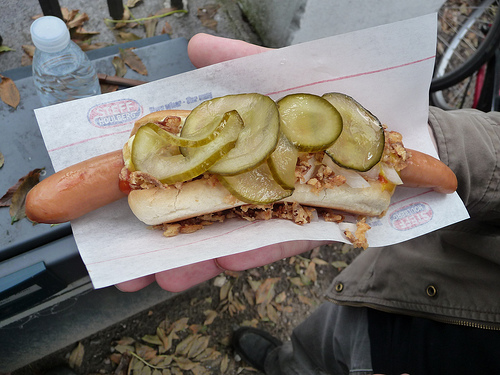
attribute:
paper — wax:
[66, 208, 381, 258]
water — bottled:
[31, 15, 102, 104]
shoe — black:
[221, 317, 318, 359]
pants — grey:
[228, 298, 370, 373]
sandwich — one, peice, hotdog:
[29, 80, 463, 227]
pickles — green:
[189, 93, 345, 161]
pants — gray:
[264, 300, 373, 374]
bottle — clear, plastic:
[22, 12, 106, 102]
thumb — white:
[183, 25, 250, 72]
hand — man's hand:
[106, 29, 437, 296]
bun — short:
[137, 111, 394, 217]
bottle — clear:
[18, 14, 102, 109]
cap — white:
[32, 19, 77, 51]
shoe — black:
[227, 323, 301, 373]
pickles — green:
[157, 90, 375, 185]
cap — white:
[30, 15, 69, 53]